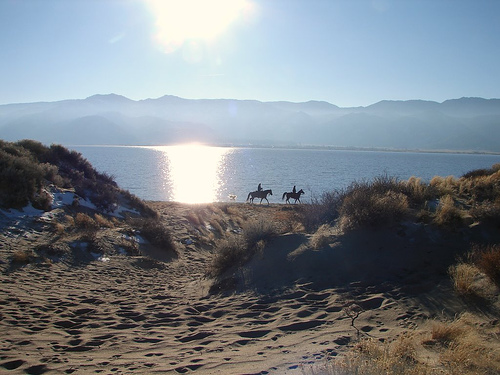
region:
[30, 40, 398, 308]
this is a beach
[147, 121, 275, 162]
the water is blue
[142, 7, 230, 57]
the sun is bright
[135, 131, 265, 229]
the water is reflecting the sun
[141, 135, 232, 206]
the sun is white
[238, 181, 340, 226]
there are two horses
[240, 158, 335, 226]
the horses are being rode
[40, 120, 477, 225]
a large body of water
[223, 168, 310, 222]
people riding horses on beach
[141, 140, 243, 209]
the sun is reflecting on the ground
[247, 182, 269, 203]
a person is riding a horse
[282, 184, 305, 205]
a person is riding a horse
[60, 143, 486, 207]
the water is calm and smooth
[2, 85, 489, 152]
a mountain range is on the horizon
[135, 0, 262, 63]
the sun is bright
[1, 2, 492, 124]
the sky is blue in color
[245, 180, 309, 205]
two riders are by the water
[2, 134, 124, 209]
bushes are on the shore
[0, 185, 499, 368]
the ground is filled with sand